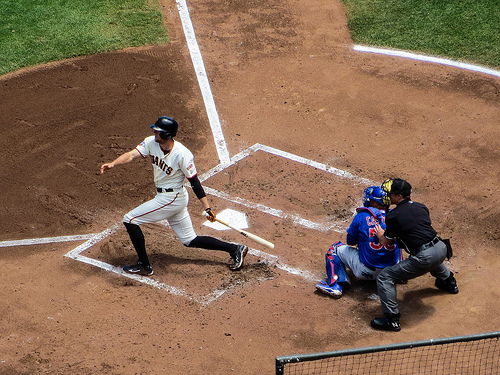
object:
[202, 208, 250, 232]
home plate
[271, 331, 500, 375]
fence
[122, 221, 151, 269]
socks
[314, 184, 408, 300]
catcher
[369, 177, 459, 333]
umpire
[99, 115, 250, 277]
player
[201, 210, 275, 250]
bat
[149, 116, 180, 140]
helmet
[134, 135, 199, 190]
uniform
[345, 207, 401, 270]
uniform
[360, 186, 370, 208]
mask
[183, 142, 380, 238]
batters box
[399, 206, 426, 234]
black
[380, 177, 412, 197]
hat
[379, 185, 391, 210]
mask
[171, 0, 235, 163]
line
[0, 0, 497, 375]
field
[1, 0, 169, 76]
grass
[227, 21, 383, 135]
dirt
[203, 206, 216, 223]
glove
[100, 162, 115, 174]
hand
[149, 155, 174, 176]
name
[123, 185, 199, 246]
pants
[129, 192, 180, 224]
stripe